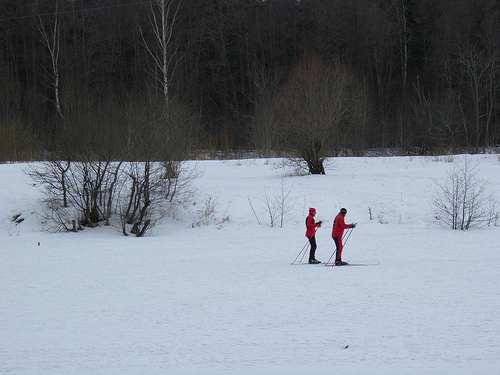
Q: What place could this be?
A: It is a field.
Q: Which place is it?
A: It is a field.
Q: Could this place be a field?
A: Yes, it is a field.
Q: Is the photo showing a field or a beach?
A: It is showing a field.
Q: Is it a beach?
A: No, it is a field.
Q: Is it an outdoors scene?
A: Yes, it is outdoors.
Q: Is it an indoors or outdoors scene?
A: It is outdoors.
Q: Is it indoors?
A: No, it is outdoors.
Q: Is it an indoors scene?
A: No, it is outdoors.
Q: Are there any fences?
A: No, there are no fences.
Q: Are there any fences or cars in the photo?
A: No, there are no fences or cars.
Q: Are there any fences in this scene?
A: No, there are no fences.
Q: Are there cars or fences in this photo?
A: No, there are no fences or cars.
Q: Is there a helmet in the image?
A: No, there are no helmets.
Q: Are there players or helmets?
A: No, there are no helmets or players.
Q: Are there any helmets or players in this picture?
A: No, there are no helmets or players.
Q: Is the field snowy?
A: Yes, the field is snowy.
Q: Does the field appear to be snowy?
A: Yes, the field is snowy.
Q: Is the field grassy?
A: No, the field is snowy.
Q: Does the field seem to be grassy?
A: No, the field is snowy.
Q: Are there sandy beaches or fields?
A: No, there is a field but it is snowy.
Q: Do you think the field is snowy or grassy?
A: The field is snowy.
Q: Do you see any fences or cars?
A: No, there are no fences or cars.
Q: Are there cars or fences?
A: No, there are no fences or cars.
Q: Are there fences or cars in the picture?
A: No, there are no fences or cars.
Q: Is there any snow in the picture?
A: Yes, there is snow.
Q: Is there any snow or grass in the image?
A: Yes, there is snow.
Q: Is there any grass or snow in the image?
A: Yes, there is snow.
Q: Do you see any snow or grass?
A: Yes, there is snow.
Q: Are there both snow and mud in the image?
A: No, there is snow but no mud.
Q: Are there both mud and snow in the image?
A: No, there is snow but no mud.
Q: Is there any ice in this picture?
A: No, there is no ice.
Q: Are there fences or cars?
A: No, there are no fences or cars.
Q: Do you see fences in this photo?
A: No, there are no fences.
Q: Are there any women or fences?
A: No, there are no fences or women.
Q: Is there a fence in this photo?
A: No, there are no fences.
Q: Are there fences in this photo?
A: No, there are no fences.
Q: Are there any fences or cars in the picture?
A: No, there are no fences or cars.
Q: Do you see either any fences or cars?
A: No, there are no fences or cars.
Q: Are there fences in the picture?
A: No, there are no fences.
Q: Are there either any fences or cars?
A: No, there are no fences or cars.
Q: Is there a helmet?
A: No, there are no helmets.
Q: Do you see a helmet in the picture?
A: No, there are no helmets.